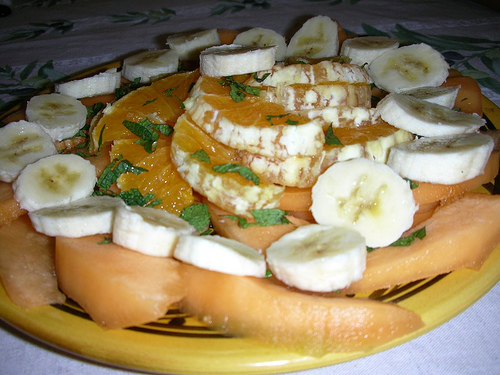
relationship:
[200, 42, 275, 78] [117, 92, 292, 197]
banana on oranges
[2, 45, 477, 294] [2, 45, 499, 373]
fruit on plate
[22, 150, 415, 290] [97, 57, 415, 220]
banana around orange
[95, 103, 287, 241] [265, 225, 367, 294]
herbs sprinkled on banana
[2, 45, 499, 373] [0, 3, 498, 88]
plate on table cloth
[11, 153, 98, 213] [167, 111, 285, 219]
banana slice around fruit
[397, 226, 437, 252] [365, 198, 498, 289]
herb on cantaloupe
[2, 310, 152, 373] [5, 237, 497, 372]
shadow of plate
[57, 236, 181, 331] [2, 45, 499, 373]
fruit on plate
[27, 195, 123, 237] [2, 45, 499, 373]
banana slice on plate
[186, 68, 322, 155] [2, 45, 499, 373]
fruit on plate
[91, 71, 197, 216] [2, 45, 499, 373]
fruit on plate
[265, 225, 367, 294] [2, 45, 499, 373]
banana on plate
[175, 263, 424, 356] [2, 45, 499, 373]
melon on plate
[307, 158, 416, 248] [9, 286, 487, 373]
banana are on plate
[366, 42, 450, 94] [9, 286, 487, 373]
banana are on plate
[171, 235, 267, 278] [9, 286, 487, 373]
banana are on plate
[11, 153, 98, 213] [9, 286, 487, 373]
banana slice are on plate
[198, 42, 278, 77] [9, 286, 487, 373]
banana are on plate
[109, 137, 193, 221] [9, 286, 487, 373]
fruit are on plate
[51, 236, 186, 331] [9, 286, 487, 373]
fruit on plate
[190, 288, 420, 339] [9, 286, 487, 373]
melon on plate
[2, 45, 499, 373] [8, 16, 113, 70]
plate on table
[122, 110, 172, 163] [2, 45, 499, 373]
chives are on plate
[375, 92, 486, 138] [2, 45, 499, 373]
banana are on plate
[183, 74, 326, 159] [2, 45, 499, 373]
fruit are on plate